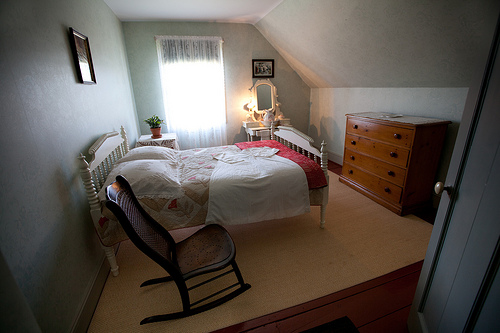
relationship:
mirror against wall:
[251, 79, 278, 118] [123, 20, 313, 134]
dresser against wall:
[342, 114, 451, 225] [309, 88, 465, 204]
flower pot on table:
[145, 115, 167, 139] [143, 133, 178, 150]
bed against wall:
[82, 121, 328, 226] [5, 7, 131, 314]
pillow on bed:
[118, 143, 178, 160] [82, 121, 328, 226]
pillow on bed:
[116, 163, 182, 199] [82, 121, 328, 226]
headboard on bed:
[80, 124, 130, 234] [82, 121, 328, 226]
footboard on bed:
[267, 124, 330, 170] [82, 121, 328, 226]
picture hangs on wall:
[66, 25, 97, 85] [5, 7, 131, 314]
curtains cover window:
[156, 38, 229, 152] [160, 34, 227, 138]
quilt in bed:
[109, 148, 213, 224] [82, 121, 328, 226]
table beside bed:
[143, 133, 178, 150] [82, 121, 328, 226]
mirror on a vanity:
[251, 79, 278, 118] [242, 81, 292, 140]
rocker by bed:
[104, 174, 252, 327] [82, 121, 328, 226]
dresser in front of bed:
[342, 114, 451, 225] [82, 121, 328, 226]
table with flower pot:
[143, 133, 178, 150] [145, 115, 167, 139]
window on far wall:
[160, 34, 227, 138] [123, 20, 313, 134]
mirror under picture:
[251, 79, 278, 118] [66, 25, 97, 85]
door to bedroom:
[410, 10, 498, 331] [1, 2, 499, 332]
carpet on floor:
[90, 158, 434, 333] [78, 156, 438, 330]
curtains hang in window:
[156, 38, 229, 152] [160, 34, 227, 138]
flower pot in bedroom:
[145, 115, 167, 139] [1, 2, 499, 332]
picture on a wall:
[66, 25, 97, 85] [5, 7, 131, 314]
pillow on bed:
[95, 158, 182, 203] [82, 121, 328, 226]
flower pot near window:
[145, 115, 167, 139] [160, 34, 227, 138]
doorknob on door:
[429, 181, 451, 198] [410, 10, 498, 331]